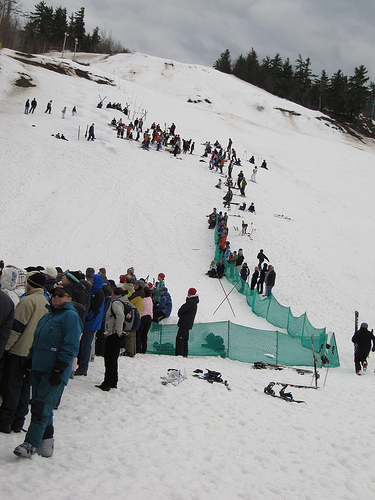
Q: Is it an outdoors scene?
A: Yes, it is outdoors.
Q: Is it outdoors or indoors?
A: It is outdoors.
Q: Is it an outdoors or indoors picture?
A: It is outdoors.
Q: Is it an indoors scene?
A: No, it is outdoors.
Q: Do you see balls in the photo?
A: No, there are no balls.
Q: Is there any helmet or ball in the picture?
A: No, there are no balls or helmets.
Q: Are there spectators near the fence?
A: Yes, there are spectators near the fence.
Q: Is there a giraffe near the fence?
A: No, there are spectators near the fence.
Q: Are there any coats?
A: Yes, there is a coat.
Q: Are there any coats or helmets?
A: Yes, there is a coat.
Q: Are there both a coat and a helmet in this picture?
A: No, there is a coat but no helmets.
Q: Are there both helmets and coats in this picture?
A: No, there is a coat but no helmets.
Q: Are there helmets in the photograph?
A: No, there are no helmets.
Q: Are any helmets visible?
A: No, there are no helmets.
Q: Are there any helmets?
A: No, there are no helmets.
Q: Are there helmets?
A: No, there are no helmets.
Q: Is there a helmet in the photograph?
A: No, there are no helmets.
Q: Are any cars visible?
A: No, there are no cars.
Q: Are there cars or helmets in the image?
A: No, there are no cars or helmets.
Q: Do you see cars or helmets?
A: No, there are no cars or helmets.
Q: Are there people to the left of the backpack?
A: Yes, there is a person to the left of the backpack.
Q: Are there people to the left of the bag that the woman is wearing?
A: Yes, there is a person to the left of the backpack.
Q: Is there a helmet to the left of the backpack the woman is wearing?
A: No, there is a person to the left of the backpack.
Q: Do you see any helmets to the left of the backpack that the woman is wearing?
A: No, there is a person to the left of the backpack.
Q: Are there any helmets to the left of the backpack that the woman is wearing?
A: No, there is a person to the left of the backpack.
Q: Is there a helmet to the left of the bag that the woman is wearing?
A: No, there is a person to the left of the backpack.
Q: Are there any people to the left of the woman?
A: Yes, there is a person to the left of the woman.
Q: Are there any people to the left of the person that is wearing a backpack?
A: Yes, there is a person to the left of the woman.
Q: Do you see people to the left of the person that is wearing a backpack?
A: Yes, there is a person to the left of the woman.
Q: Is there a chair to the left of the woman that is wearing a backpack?
A: No, there is a person to the left of the woman.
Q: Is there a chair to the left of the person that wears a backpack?
A: No, there is a person to the left of the woman.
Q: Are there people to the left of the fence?
A: Yes, there is a person to the left of the fence.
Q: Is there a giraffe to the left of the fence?
A: No, there is a person to the left of the fence.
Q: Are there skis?
A: Yes, there are skis.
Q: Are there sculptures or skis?
A: Yes, there are skis.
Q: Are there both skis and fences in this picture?
A: Yes, there are both skis and a fence.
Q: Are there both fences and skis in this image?
A: Yes, there are both skis and a fence.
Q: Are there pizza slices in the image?
A: No, there are no pizza slices.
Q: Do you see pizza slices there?
A: No, there are no pizza slices.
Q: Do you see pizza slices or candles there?
A: No, there are no pizza slices or candles.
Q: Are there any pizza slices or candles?
A: No, there are no pizza slices or candles.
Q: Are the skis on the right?
A: Yes, the skis are on the right of the image.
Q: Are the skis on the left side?
A: No, the skis are on the right of the image.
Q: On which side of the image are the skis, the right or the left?
A: The skis are on the right of the image.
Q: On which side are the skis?
A: The skis are on the right of the image.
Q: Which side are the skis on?
A: The skis are on the right of the image.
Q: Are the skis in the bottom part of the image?
A: Yes, the skis are in the bottom of the image.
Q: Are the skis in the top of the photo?
A: No, the skis are in the bottom of the image.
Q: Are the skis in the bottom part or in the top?
A: The skis are in the bottom of the image.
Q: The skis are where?
A: The skis are in the snow.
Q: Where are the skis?
A: The skis are in the snow.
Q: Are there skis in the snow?
A: Yes, there are skis in the snow.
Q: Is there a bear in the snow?
A: No, there are skis in the snow.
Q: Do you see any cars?
A: No, there are no cars.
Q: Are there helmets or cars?
A: No, there are no cars or helmets.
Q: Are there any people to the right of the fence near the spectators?
A: Yes, there is a person to the right of the fence.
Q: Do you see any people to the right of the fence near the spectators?
A: Yes, there is a person to the right of the fence.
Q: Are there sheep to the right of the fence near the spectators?
A: No, there is a person to the right of the fence.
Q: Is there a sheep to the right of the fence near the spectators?
A: No, there is a person to the right of the fence.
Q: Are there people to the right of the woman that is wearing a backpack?
A: Yes, there is a person to the right of the woman.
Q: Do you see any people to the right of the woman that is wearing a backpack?
A: Yes, there is a person to the right of the woman.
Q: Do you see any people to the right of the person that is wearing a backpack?
A: Yes, there is a person to the right of the woman.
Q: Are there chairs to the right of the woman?
A: No, there is a person to the right of the woman.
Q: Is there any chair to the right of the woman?
A: No, there is a person to the right of the woman.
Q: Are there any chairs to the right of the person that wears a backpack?
A: No, there is a person to the right of the woman.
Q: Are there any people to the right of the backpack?
A: Yes, there is a person to the right of the backpack.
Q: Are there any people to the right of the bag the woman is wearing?
A: Yes, there is a person to the right of the backpack.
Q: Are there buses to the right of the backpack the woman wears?
A: No, there is a person to the right of the backpack.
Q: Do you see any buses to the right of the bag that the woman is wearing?
A: No, there is a person to the right of the backpack.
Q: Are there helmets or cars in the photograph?
A: No, there are no helmets or cars.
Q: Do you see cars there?
A: No, there are no cars.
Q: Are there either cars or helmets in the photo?
A: No, there are no cars or helmets.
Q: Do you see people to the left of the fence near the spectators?
A: Yes, there is a person to the left of the fence.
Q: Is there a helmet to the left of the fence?
A: No, there is a person to the left of the fence.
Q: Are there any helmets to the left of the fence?
A: No, there is a person to the left of the fence.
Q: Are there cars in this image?
A: No, there are no cars.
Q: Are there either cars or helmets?
A: No, there are no cars or helmets.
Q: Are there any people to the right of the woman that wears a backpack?
A: Yes, there is a person to the right of the woman.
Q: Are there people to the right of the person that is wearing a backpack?
A: Yes, there is a person to the right of the woman.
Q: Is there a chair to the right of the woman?
A: No, there is a person to the right of the woman.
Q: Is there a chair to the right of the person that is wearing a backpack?
A: No, there is a person to the right of the woman.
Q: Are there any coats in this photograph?
A: Yes, there is a coat.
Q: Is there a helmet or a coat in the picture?
A: Yes, there is a coat.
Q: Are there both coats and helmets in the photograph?
A: No, there is a coat but no helmets.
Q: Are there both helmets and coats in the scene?
A: No, there is a coat but no helmets.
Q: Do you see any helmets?
A: No, there are no helmets.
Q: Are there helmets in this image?
A: No, there are no helmets.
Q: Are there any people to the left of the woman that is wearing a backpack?
A: Yes, there is a person to the left of the woman.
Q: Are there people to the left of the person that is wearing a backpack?
A: Yes, there is a person to the left of the woman.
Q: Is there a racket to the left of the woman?
A: No, there is a person to the left of the woman.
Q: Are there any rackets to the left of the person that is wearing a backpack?
A: No, there is a person to the left of the woman.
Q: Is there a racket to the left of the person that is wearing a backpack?
A: No, there is a person to the left of the woman.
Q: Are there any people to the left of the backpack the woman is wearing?
A: Yes, there is a person to the left of the backpack.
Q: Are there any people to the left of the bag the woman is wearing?
A: Yes, there is a person to the left of the backpack.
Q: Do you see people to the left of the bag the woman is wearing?
A: Yes, there is a person to the left of the backpack.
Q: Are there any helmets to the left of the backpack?
A: No, there is a person to the left of the backpack.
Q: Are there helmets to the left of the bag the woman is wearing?
A: No, there is a person to the left of the backpack.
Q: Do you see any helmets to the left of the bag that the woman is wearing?
A: No, there is a person to the left of the backpack.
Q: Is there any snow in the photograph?
A: Yes, there is snow.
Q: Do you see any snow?
A: Yes, there is snow.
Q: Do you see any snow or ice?
A: Yes, there is snow.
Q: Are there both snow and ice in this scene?
A: No, there is snow but no ice.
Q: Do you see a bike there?
A: No, there are no bikes.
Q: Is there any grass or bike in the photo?
A: No, there are no bikes or grass.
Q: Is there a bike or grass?
A: No, there are no bikes or grass.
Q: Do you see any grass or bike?
A: No, there are no bikes or grass.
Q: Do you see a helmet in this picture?
A: No, there are no helmets.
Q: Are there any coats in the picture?
A: Yes, there is a coat.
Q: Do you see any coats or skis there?
A: Yes, there is a coat.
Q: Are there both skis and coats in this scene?
A: Yes, there are both a coat and skis.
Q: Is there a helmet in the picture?
A: No, there are no helmets.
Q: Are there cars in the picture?
A: No, there are no cars.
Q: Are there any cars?
A: No, there are no cars.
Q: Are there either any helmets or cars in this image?
A: No, there are no cars or helmets.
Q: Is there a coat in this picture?
A: Yes, there is a coat.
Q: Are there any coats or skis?
A: Yes, there is a coat.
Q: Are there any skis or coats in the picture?
A: Yes, there is a coat.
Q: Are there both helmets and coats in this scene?
A: No, there is a coat but no helmets.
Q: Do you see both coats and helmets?
A: No, there is a coat but no helmets.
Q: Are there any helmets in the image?
A: No, there are no helmets.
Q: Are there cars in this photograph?
A: No, there are no cars.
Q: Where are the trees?
A: The trees are on the hill.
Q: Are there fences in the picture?
A: Yes, there is a fence.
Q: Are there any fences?
A: Yes, there is a fence.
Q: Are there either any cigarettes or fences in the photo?
A: Yes, there is a fence.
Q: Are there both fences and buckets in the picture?
A: No, there is a fence but no buckets.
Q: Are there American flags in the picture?
A: No, there are no American flags.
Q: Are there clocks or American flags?
A: No, there are no American flags or clocks.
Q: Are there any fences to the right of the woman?
A: Yes, there is a fence to the right of the woman.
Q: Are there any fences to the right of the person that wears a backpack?
A: Yes, there is a fence to the right of the woman.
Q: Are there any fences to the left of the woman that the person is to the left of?
A: No, the fence is to the right of the woman.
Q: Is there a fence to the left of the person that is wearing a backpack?
A: No, the fence is to the right of the woman.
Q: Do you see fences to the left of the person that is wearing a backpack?
A: No, the fence is to the right of the woman.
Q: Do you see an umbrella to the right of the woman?
A: No, there is a fence to the right of the woman.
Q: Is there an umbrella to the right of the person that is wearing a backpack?
A: No, there is a fence to the right of the woman.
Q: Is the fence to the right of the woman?
A: Yes, the fence is to the right of the woman.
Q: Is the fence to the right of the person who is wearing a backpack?
A: Yes, the fence is to the right of the woman.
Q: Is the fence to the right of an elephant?
A: No, the fence is to the right of the woman.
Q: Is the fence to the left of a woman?
A: No, the fence is to the right of a woman.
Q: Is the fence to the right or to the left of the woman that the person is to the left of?
A: The fence is to the right of the woman.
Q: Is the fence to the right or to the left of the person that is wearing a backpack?
A: The fence is to the right of the woman.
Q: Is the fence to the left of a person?
A: Yes, the fence is to the left of a person.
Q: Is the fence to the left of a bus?
A: No, the fence is to the left of a person.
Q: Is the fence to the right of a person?
A: No, the fence is to the left of a person.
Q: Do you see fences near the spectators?
A: Yes, there is a fence near the spectators.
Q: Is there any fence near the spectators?
A: Yes, there is a fence near the spectators.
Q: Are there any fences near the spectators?
A: Yes, there is a fence near the spectators.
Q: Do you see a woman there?
A: Yes, there is a woman.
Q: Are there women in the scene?
A: Yes, there is a woman.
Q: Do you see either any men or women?
A: Yes, there is a woman.